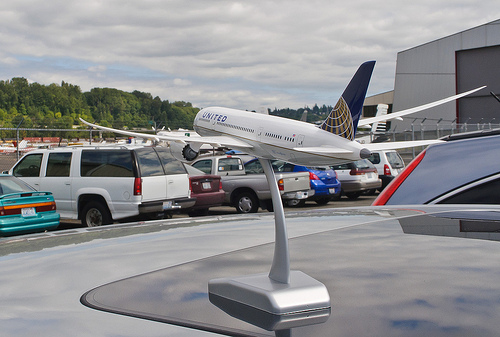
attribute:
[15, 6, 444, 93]
sky — blue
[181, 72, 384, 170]
jet — white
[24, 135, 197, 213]
vehicle — white, large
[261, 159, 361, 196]
car — blue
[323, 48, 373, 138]
tail — blue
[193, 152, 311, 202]
truck — white, silver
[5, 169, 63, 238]
car — green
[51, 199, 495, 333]
car — white, grey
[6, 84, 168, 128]
trees — forest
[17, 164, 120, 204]
cars — parked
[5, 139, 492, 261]
parking lot — cars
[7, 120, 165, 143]
fence — chain link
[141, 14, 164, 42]
clouds — white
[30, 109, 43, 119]
leaves — green